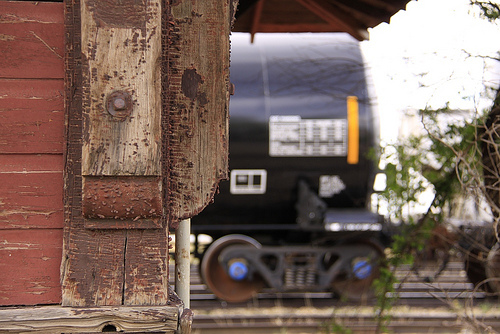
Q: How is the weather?
A: Clear.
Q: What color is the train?
A: Black.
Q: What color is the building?
A: Red.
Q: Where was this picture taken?
A: A station.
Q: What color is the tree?
A: Green.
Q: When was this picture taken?
A: Daytime.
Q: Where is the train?
A: The train tracks.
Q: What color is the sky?
A: White.